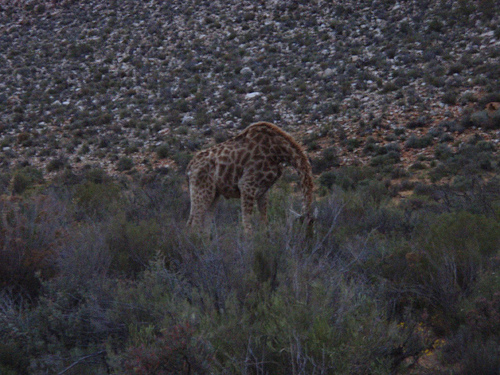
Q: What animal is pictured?
A: A giraffe.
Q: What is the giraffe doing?
A: Eating.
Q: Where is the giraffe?
A: A field.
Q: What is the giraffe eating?
A: The grass.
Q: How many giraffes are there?
A: One.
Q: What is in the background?
A: A hill.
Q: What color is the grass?
A: Green.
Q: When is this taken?
A: Dusk.